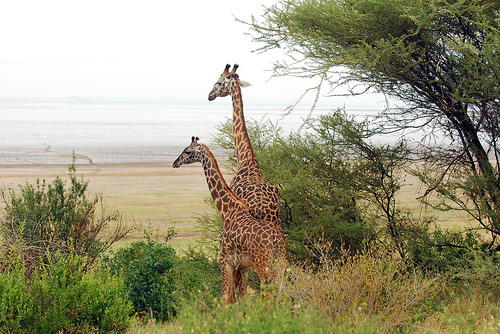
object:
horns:
[218, 63, 233, 75]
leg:
[219, 265, 232, 306]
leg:
[237, 265, 248, 297]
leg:
[258, 264, 271, 294]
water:
[0, 120, 499, 165]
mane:
[202, 143, 250, 210]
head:
[172, 136, 208, 171]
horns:
[189, 136, 195, 144]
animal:
[173, 135, 286, 306]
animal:
[209, 63, 280, 223]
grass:
[120, 253, 497, 332]